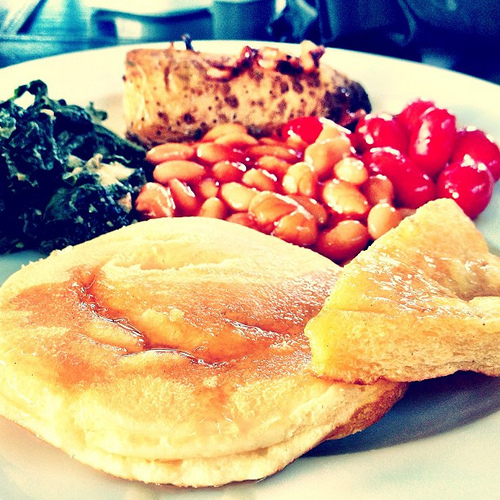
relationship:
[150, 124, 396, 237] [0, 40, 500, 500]
bean on plate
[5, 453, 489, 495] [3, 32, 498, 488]
plate with food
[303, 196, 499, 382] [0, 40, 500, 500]
bread on plate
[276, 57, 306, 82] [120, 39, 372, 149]
burn marks on food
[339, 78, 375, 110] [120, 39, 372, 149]
burn marks on food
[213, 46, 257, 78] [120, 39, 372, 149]
burn marks on food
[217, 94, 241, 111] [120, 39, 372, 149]
burn marks on food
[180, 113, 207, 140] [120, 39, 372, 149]
burn marks on food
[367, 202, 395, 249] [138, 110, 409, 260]
bean in sauce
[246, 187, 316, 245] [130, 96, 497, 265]
brown bean in sauce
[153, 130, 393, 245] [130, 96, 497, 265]
brown bean in sauce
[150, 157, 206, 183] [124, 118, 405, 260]
bean in sauce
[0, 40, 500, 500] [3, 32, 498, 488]
plate full of food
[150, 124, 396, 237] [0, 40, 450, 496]
bean on plate